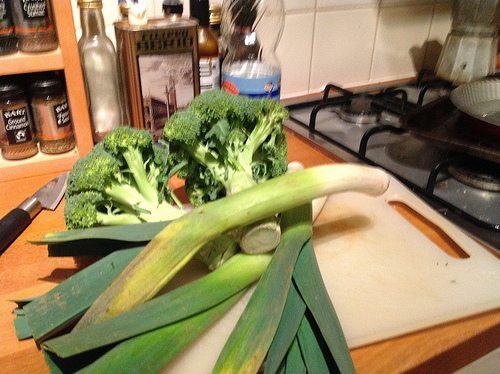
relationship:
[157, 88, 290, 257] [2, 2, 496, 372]
broccoli are in kitchen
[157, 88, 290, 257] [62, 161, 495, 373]
broccoli are on top of cutting board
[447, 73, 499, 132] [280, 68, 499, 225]
pie pan on top of stove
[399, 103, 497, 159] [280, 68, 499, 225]
cookie sheet on top of stove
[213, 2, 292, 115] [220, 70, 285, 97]
vegetable oil has blue label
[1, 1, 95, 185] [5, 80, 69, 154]
spice rack has spices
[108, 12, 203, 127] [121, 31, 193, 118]
olive oil in gold can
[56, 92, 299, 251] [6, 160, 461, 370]
broccoli on top of counter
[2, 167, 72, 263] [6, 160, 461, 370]
knife on top of counter